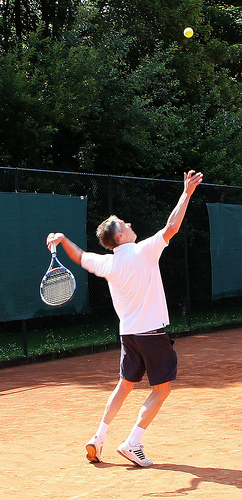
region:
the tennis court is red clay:
[3, 322, 240, 497]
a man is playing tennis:
[35, 166, 205, 467]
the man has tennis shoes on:
[84, 434, 151, 468]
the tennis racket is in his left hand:
[36, 227, 79, 305]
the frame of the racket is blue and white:
[33, 231, 78, 308]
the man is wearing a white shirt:
[80, 233, 171, 335]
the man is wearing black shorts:
[118, 326, 178, 384]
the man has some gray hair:
[94, 213, 138, 247]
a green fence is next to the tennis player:
[0, 164, 240, 331]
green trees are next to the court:
[0, 58, 240, 310]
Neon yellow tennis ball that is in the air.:
[183, 25, 194, 38]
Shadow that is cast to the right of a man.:
[91, 459, 241, 492]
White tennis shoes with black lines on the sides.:
[84, 434, 154, 466]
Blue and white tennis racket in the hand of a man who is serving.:
[39, 238, 75, 306]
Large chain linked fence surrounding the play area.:
[0, 165, 241, 366]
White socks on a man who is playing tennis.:
[95, 421, 146, 446]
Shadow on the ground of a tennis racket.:
[140, 488, 188, 496]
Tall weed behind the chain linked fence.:
[43, 327, 57, 351]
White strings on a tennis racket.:
[45, 277, 69, 299]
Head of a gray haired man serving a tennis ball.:
[95, 214, 136, 249]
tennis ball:
[183, 26, 194, 36]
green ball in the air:
[177, 24, 203, 41]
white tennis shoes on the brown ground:
[116, 441, 155, 466]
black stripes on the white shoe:
[132, 447, 144, 458]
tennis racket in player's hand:
[38, 229, 78, 308]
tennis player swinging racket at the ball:
[38, 168, 205, 468]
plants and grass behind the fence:
[4, 321, 86, 352]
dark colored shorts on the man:
[118, 328, 178, 388]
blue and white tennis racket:
[40, 248, 75, 311]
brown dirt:
[0, 394, 84, 499]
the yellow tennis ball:
[179, 25, 199, 41]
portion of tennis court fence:
[116, 185, 170, 210]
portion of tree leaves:
[23, 55, 121, 108]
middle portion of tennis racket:
[35, 264, 78, 312]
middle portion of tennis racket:
[48, 253, 65, 267]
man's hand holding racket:
[42, 230, 63, 247]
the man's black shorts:
[122, 334, 171, 379]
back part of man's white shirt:
[114, 257, 163, 325]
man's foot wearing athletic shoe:
[118, 442, 151, 468]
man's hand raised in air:
[165, 169, 203, 241]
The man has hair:
[72, 200, 147, 256]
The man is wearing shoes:
[77, 425, 161, 477]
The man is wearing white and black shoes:
[72, 412, 171, 484]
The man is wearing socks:
[85, 408, 154, 443]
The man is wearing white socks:
[84, 412, 173, 440]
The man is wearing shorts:
[109, 321, 192, 398]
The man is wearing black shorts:
[105, 322, 171, 384]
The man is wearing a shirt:
[64, 236, 188, 350]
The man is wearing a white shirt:
[58, 230, 189, 339]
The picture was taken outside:
[1, 12, 239, 492]